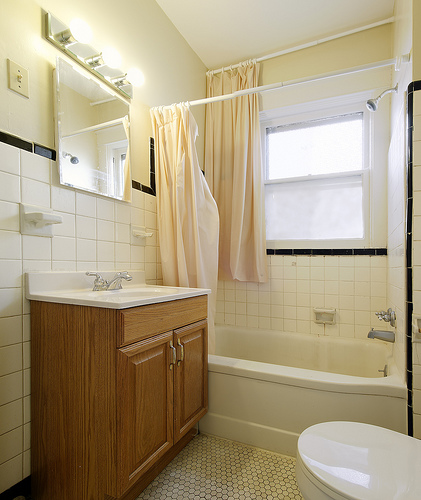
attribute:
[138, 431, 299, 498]
hexagonal tiles — Hexagonal , small 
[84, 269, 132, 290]
faucet — silver, metal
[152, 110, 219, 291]
shower curtain — peach 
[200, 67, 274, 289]
window curtain — peach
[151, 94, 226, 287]
curtain — beige, opened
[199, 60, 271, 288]
curtain — peach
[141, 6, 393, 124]
rod — higher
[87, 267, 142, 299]
faucet — silver, double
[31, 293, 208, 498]
brown cabinets — wood